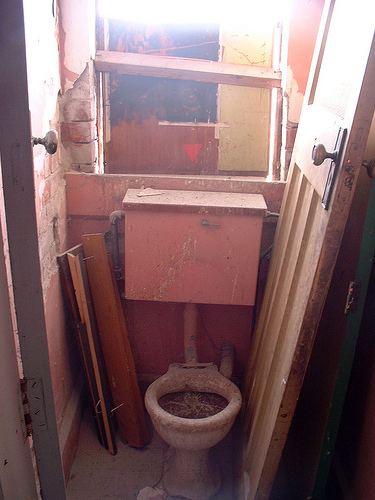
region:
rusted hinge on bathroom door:
[15, 374, 49, 442]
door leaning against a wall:
[235, 0, 374, 499]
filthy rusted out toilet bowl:
[142, 358, 243, 496]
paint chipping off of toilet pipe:
[180, 302, 202, 366]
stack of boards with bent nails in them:
[54, 230, 154, 457]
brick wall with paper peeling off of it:
[0, 0, 98, 459]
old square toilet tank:
[120, 187, 267, 307]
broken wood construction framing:
[94, 48, 282, 89]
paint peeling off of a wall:
[283, 63, 307, 124]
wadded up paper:
[134, 483, 168, 499]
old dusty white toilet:
[144, 362, 240, 499]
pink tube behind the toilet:
[185, 301, 196, 362]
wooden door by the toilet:
[237, 0, 373, 499]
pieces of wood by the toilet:
[52, 233, 151, 453]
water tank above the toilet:
[122, 189, 264, 305]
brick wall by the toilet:
[23, 1, 102, 495]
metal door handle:
[312, 144, 326, 164]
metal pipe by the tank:
[111, 210, 124, 293]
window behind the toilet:
[96, 1, 278, 180]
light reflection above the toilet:
[97, 1, 282, 27]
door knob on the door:
[42, 131, 65, 160]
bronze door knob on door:
[306, 137, 338, 171]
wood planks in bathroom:
[57, 231, 135, 450]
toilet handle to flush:
[193, 220, 227, 231]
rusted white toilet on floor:
[147, 359, 241, 496]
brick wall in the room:
[63, 90, 97, 171]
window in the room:
[106, 66, 271, 181]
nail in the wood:
[106, 400, 125, 415]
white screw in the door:
[25, 381, 47, 393]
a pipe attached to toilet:
[107, 204, 126, 280]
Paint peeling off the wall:
[69, 99, 90, 133]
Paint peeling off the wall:
[66, 159, 85, 185]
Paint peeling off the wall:
[98, 173, 123, 189]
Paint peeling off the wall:
[89, 180, 134, 226]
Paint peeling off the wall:
[131, 174, 172, 195]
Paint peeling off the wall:
[176, 167, 288, 203]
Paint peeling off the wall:
[133, 245, 203, 303]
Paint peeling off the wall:
[48, 113, 67, 137]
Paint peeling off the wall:
[122, 92, 171, 142]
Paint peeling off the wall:
[53, 349, 79, 439]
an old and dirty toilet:
[79, 106, 312, 499]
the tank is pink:
[89, 177, 302, 312]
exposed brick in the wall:
[30, 6, 106, 222]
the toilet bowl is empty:
[131, 348, 260, 496]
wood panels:
[53, 220, 164, 471]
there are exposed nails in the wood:
[84, 241, 127, 443]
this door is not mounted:
[216, 5, 371, 498]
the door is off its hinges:
[233, 3, 369, 499]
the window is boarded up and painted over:
[95, 2, 286, 197]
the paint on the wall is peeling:
[30, 7, 97, 376]